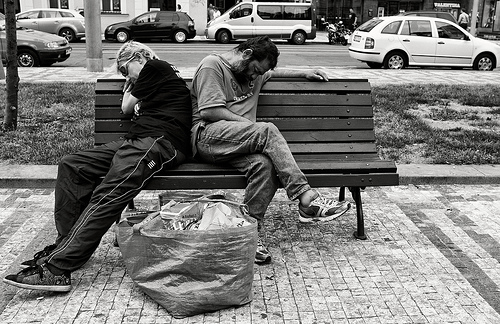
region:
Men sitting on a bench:
[55, 23, 372, 318]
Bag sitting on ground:
[110, 188, 272, 322]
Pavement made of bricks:
[331, 252, 441, 319]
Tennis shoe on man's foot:
[288, 176, 353, 243]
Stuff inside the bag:
[141, 178, 251, 258]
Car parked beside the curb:
[353, 14, 498, 86]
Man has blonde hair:
[103, 43, 190, 96]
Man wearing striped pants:
[35, 130, 168, 285]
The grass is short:
[40, 90, 87, 143]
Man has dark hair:
[240, 38, 291, 89]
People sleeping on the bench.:
[109, 44, 286, 184]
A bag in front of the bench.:
[141, 198, 268, 309]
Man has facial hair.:
[224, 58, 245, 90]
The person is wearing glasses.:
[113, 63, 127, 78]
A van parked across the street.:
[205, 10, 357, 45]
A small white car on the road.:
[348, 17, 484, 69]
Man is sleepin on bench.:
[203, 57, 298, 207]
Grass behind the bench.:
[388, 88, 470, 158]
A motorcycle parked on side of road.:
[323, 10, 360, 50]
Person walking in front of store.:
[451, 12, 463, 33]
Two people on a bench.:
[3, 33, 351, 294]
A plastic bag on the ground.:
[113, 195, 259, 322]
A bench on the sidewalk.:
[91, 77, 400, 240]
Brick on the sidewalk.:
[2, 185, 497, 320]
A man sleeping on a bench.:
[188, 35, 351, 265]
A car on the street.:
[347, 14, 499, 70]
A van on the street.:
[205, 1, 318, 44]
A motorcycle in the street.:
[318, 13, 350, 45]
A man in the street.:
[456, 6, 469, 28]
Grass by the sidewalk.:
[0, 80, 499, 165]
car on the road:
[351, 12, 495, 74]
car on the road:
[206, 0, 311, 41]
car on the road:
[107, 8, 191, 39]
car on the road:
[13, 0, 87, 35]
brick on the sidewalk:
[298, 295, 310, 317]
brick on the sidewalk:
[318, 301, 336, 320]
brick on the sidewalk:
[368, 294, 383, 314]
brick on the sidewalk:
[420, 303, 434, 317]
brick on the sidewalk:
[318, 262, 341, 278]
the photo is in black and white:
[30, 28, 375, 294]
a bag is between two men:
[106, 204, 271, 299]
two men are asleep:
[95, 41, 298, 147]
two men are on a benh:
[100, 29, 411, 216]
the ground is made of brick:
[291, 252, 381, 322]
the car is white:
[342, 5, 490, 87]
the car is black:
[98, 8, 257, 48]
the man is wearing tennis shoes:
[261, 195, 496, 284]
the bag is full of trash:
[105, 209, 307, 287]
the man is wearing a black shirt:
[95, 48, 278, 161]